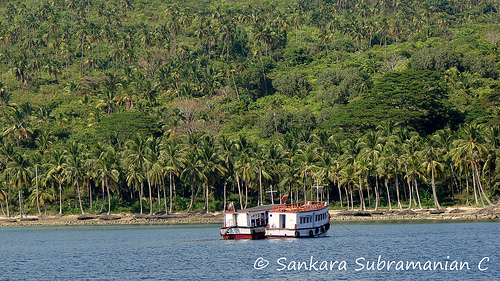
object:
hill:
[0, 0, 499, 216]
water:
[0, 221, 499, 281]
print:
[253, 253, 492, 273]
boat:
[219, 203, 286, 241]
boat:
[264, 200, 330, 239]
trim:
[225, 234, 257, 242]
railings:
[268, 201, 328, 213]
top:
[274, 200, 325, 211]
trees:
[94, 109, 165, 146]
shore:
[0, 205, 500, 226]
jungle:
[0, 0, 499, 209]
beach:
[0, 206, 498, 226]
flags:
[225, 200, 234, 212]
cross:
[264, 185, 277, 205]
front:
[255, 198, 280, 210]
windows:
[298, 215, 300, 224]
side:
[299, 212, 336, 238]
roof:
[267, 200, 332, 214]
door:
[279, 213, 287, 229]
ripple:
[0, 222, 498, 281]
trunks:
[5, 192, 492, 216]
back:
[267, 214, 297, 236]